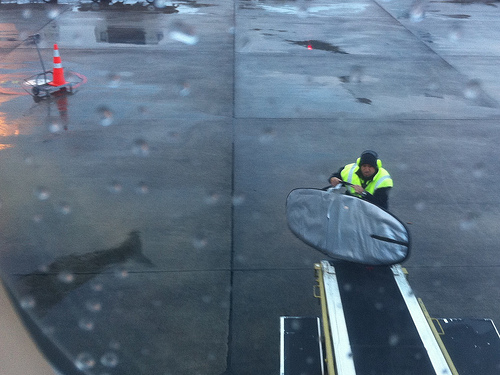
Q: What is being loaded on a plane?
A: Surfboard.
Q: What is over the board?
A: A cover.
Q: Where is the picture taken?
A: Airport tarmac.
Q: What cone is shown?
A: An orange one.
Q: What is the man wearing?
A: Safety vest.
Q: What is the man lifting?
A: An oval silver bag.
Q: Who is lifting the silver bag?
A: A man.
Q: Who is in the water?
A: A man.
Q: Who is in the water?
A: A man.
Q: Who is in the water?
A: A man.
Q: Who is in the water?
A: A man.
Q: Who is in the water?
A: A man.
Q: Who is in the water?
A: A man.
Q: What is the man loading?
A: Luggage.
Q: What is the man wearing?
A: Yellow safety vest.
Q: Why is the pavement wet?
A: It is raining.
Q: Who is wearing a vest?
A: Baggage handler.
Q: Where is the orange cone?
A: On the runway.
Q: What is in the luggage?
A: Surfboard.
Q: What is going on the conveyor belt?
A: The luggage.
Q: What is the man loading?
A: Luggage.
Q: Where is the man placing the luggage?
A: Conveyor belt.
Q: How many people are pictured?
A: 1.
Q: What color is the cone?
A: Orange.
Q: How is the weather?
A: Wet.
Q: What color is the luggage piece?
A: Silver.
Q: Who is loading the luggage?
A: Baggage handler.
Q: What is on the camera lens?
A: Water drops.